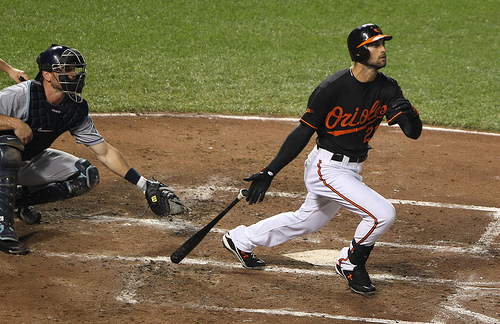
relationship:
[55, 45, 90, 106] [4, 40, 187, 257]
mask of catcher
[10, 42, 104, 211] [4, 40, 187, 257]
gear on catcher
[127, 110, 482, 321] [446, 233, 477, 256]
box lined chalk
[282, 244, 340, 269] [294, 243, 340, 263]
home plate has dirt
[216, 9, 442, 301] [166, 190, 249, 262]
player has swung bat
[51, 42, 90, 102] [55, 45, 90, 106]
face protected mask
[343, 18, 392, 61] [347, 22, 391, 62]
head wearing hat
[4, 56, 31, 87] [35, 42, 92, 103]
hand behind head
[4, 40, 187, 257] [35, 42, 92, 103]
catcher has head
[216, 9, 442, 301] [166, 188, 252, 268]
player dropping bat